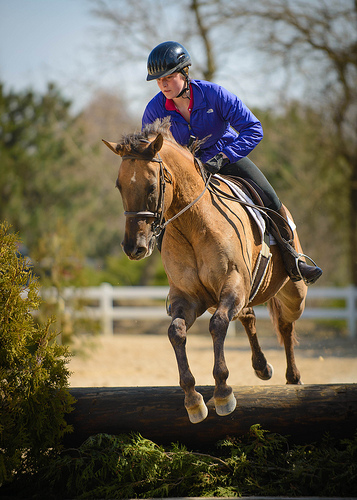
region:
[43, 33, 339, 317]
a woman riding a horse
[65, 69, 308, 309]
a woman riding a brown horse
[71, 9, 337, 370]
a woman sittin gon a horse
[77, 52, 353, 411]
a woman sittin gon a brown horse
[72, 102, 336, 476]
a horse jumping over a log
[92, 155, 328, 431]
a brown horse jumping over log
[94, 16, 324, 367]
a horse with a rider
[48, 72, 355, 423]
a brown horse with rider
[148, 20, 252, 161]
a woman wearing a helemt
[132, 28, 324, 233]
a woman wearing a jacket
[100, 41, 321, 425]
A woman riding a brown horse.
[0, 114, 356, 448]
The horse is jumping over a wooden log.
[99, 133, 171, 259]
A bridle on the horse's head.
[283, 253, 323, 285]
The rider's foot in a metal stirrup.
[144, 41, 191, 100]
Riding helmet helmet strapped onto the rider's head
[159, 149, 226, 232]
Horse reins in the rider's hand.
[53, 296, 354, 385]
The ground is dirt.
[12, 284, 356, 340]
A white fence behind the horse.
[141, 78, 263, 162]
The rider is wearing a blue jacket.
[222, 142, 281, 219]
The rider is wearing black riding pants.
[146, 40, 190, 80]
A black helmet reflecting sunlight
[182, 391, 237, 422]
Front hooves of a horse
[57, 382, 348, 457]
Dark log laying on the ground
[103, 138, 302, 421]
Brown horse leaping an obstacle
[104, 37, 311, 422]
A woman jumps her horse over an obstacle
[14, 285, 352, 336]
A white, wooden fence in the background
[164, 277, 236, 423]
Front legs on a brown horse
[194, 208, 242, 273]
Brown fur on a horse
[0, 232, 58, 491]
Green foliage near a tree log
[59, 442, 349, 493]
Green leaves under a tree trunk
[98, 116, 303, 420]
brown horse jumping a log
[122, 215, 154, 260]
brown nose of horse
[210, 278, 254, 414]
brown leg of horse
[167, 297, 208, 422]
brown leg of horse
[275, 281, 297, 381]
brown leg of horse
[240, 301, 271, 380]
brown leg of horse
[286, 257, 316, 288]
black boot of rider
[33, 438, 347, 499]
greenery beneath log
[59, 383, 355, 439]
large brown log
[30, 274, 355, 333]
white wood fence behind horse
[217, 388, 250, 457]
There is a gray hoof to this horse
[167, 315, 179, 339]
There are brown knees on this horse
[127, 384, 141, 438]
There is a large trunk of a tree here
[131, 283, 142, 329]
There is a white fence that is in the background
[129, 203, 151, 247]
There is a bridle that is on this horse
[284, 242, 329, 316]
There is a black boot that is on this rider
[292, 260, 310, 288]
There is a steel opening for the foot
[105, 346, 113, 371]
There is light brown ground that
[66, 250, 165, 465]
Jackson Mingus took this photo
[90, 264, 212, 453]
There is the season of summer here